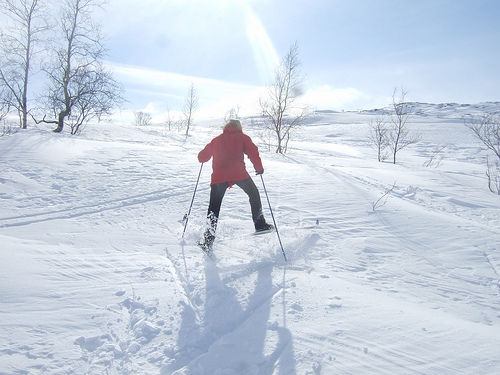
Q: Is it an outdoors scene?
A: Yes, it is outdoors.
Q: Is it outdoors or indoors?
A: It is outdoors.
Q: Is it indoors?
A: No, it is outdoors.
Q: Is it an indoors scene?
A: No, it is outdoors.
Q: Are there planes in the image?
A: No, there are no planes.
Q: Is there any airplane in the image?
A: No, there are no airplanes.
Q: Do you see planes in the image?
A: No, there are no planes.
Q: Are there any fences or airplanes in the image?
A: No, there are no airplanes or fences.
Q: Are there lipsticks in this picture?
A: No, there are no lipsticks.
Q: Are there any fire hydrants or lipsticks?
A: No, there are no lipsticks or fire hydrants.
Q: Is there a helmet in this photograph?
A: No, there are no helmets.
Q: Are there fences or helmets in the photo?
A: No, there are no helmets or fences.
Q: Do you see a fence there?
A: No, there are no fences.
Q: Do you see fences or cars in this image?
A: No, there are no fences or cars.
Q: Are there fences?
A: No, there are no fences.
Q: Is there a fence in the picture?
A: No, there are no fences.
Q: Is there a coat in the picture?
A: Yes, there is a coat.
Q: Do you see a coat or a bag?
A: Yes, there is a coat.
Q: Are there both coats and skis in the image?
A: Yes, there are both a coat and skis.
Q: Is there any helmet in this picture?
A: No, there are no helmets.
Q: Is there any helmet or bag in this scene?
A: No, there are no helmets or bags.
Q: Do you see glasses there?
A: No, there are no glasses.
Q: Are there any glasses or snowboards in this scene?
A: No, there are no glasses or snowboards.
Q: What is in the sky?
A: The clouds are in the sky.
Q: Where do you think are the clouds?
A: The clouds are in the sky.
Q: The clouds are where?
A: The clouds are in the sky.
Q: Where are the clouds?
A: The clouds are in the sky.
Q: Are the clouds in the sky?
A: Yes, the clouds are in the sky.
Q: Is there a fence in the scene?
A: No, there are no fences.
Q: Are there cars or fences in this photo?
A: No, there are no fences or cars.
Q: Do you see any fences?
A: No, there are no fences.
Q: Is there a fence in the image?
A: No, there are no fences.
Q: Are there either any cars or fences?
A: No, there are no fences or cars.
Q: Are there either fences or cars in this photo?
A: No, there are no fences or cars.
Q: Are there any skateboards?
A: No, there are no skateboards.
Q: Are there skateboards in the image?
A: No, there are no skateboards.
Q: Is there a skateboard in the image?
A: No, there are no skateboards.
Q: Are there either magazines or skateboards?
A: No, there are no skateboards or magazines.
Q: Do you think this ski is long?
A: Yes, the ski is long.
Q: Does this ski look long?
A: Yes, the ski is long.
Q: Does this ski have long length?
A: Yes, the ski is long.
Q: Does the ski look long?
A: Yes, the ski is long.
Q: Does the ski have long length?
A: Yes, the ski is long.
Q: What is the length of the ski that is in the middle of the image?
A: The ski is long.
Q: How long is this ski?
A: The ski is long.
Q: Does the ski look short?
A: No, the ski is long.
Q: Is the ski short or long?
A: The ski is long.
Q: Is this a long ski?
A: Yes, this is a long ski.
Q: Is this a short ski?
A: No, this is a long ski.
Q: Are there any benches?
A: No, there are no benches.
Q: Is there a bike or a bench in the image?
A: No, there are no benches or bikes.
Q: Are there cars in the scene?
A: No, there are no cars.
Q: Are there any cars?
A: No, there are no cars.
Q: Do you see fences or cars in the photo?
A: No, there are no cars or fences.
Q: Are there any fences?
A: No, there are no fences.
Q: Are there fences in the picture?
A: No, there are no fences.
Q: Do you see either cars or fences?
A: No, there are no fences or cars.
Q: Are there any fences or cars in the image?
A: No, there are no fences or cars.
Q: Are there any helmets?
A: No, there are no helmets.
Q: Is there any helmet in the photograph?
A: No, there are no helmets.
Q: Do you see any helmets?
A: No, there are no helmets.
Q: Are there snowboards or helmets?
A: No, there are no helmets or snowboards.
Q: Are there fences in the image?
A: No, there are no fences.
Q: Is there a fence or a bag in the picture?
A: No, there are no fences or bags.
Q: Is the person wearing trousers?
A: Yes, the person is wearing trousers.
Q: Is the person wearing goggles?
A: No, the person is wearing trousers.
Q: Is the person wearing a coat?
A: Yes, the person is wearing a coat.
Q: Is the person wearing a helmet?
A: No, the person is wearing a coat.